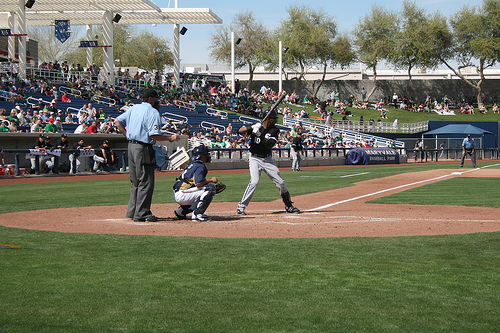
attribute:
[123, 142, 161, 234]
pants — gray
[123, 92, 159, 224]
umpire — ready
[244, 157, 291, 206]
pants — white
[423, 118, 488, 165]
tent — blue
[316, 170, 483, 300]
lines — white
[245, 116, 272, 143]
gloves — white 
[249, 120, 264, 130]
glove — white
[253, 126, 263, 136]
glove — white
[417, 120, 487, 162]
tent — blue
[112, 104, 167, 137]
shirt — blue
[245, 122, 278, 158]
shirt — black, white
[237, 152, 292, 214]
pants — gray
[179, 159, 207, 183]
top — white, blue